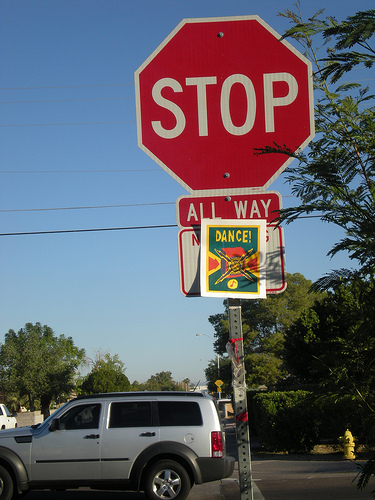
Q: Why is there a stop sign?
A: So cars don't get into accidents.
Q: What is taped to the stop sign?
A: Event flyer.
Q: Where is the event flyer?
A: Taped to the stop sign.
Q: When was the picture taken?
A: On a sunny day.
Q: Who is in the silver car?
A: Driver.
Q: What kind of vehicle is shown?
A: Car.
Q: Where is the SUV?
A: In the street.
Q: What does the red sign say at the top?
A: Stop.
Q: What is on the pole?
A: Stop sign.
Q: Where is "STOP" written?
A: On red sign.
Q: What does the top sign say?
A: Stop.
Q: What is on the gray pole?
A: Red ribbon.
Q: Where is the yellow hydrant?
A: In front of the trees.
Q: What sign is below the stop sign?
A: The all way sign.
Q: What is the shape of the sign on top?
A: Octagon.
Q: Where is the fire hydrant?
A: In front of bush.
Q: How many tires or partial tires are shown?
A: Two.